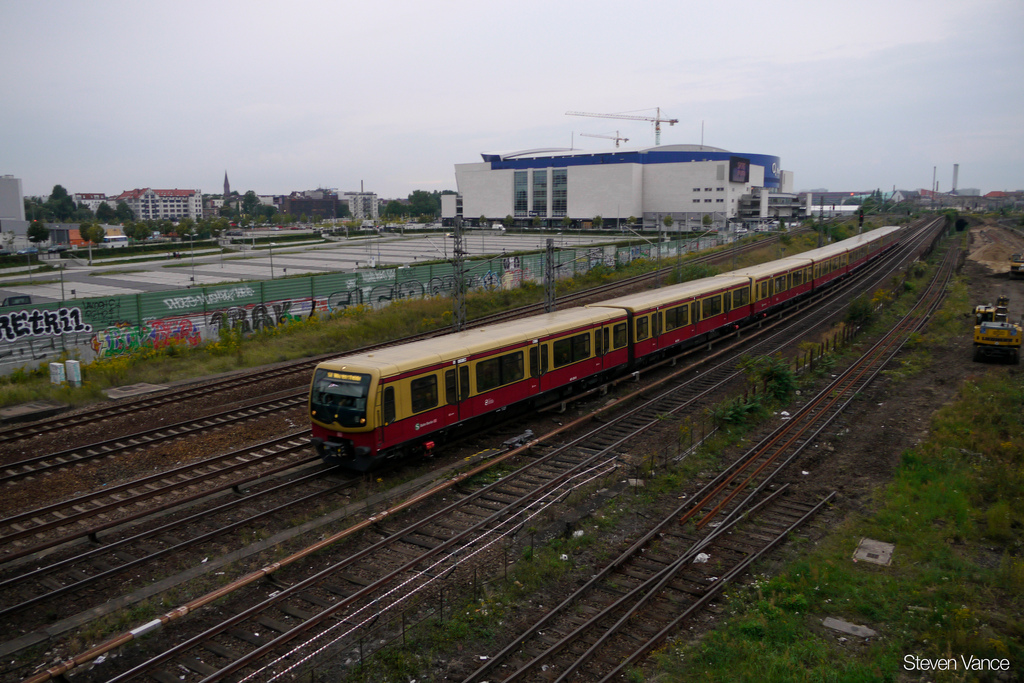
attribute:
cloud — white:
[325, 0, 346, 65]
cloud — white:
[391, 82, 458, 127]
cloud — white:
[101, 70, 156, 131]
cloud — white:
[849, 28, 927, 73]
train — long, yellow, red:
[299, 301, 636, 464]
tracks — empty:
[477, 206, 980, 675]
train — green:
[582, 265, 778, 374]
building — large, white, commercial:
[443, 137, 808, 232]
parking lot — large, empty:
[0, 216, 653, 297]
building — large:
[114, 183, 206, 234]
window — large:
[307, 358, 374, 432]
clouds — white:
[344, 51, 462, 91]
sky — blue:
[699, 19, 909, 136]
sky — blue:
[10, 8, 1015, 197]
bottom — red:
[310, 235, 905, 467]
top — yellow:
[327, 216, 894, 428]